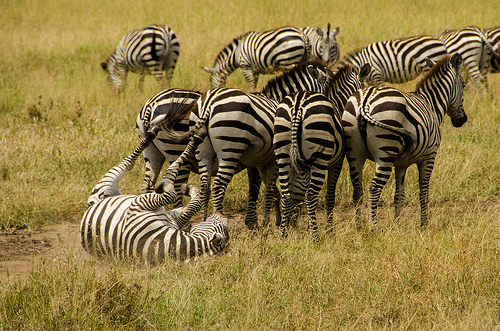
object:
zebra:
[75, 123, 243, 266]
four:
[132, 84, 414, 166]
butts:
[269, 90, 339, 168]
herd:
[0, 0, 500, 287]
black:
[366, 101, 404, 116]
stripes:
[372, 131, 408, 146]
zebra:
[96, 20, 183, 96]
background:
[0, 0, 377, 80]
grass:
[0, 30, 84, 207]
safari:
[0, 0, 500, 324]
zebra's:
[158, 84, 217, 144]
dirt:
[0, 212, 94, 296]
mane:
[412, 53, 458, 91]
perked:
[321, 65, 336, 78]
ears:
[356, 61, 374, 83]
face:
[314, 33, 342, 65]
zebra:
[299, 19, 343, 69]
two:
[328, 24, 500, 85]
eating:
[324, 33, 451, 87]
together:
[128, 52, 474, 244]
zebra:
[339, 53, 473, 234]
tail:
[145, 28, 173, 66]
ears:
[205, 229, 223, 244]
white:
[375, 113, 401, 119]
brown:
[431, 54, 452, 74]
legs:
[412, 158, 436, 229]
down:
[76, 172, 237, 279]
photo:
[0, 0, 500, 331]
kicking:
[99, 119, 213, 210]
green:
[28, 42, 91, 78]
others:
[132, 51, 471, 244]